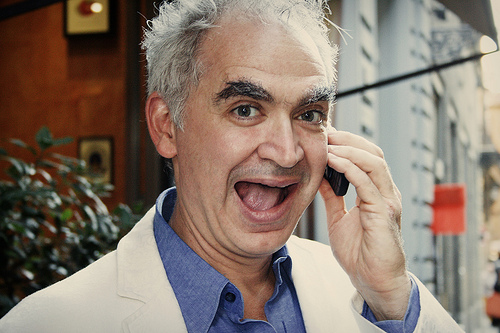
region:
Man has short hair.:
[158, 16, 249, 51]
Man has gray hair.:
[133, 21, 208, 83]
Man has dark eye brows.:
[215, 66, 336, 101]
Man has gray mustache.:
[239, 160, 334, 185]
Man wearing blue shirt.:
[204, 254, 245, 326]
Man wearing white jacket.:
[76, 267, 136, 323]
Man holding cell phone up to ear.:
[311, 111, 364, 200]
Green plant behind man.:
[17, 165, 82, 258]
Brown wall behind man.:
[14, 59, 84, 118]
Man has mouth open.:
[230, 162, 332, 232]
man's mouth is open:
[223, 171, 305, 227]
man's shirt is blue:
[156, 227, 278, 329]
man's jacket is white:
[21, 216, 447, 331]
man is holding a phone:
[311, 129, 366, 197]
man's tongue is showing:
[229, 183, 297, 225]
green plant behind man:
[3, 103, 155, 310]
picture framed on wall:
[61, 99, 118, 205]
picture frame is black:
[70, 123, 135, 203]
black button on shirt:
[221, 282, 241, 307]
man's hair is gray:
[140, 0, 400, 134]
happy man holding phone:
[114, 19, 408, 314]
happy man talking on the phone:
[123, 14, 414, 326]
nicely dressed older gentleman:
[58, 25, 425, 329]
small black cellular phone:
[324, 157, 349, 195]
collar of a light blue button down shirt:
[157, 228, 299, 332]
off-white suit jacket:
[6, 231, 453, 330]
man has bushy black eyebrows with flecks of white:
[214, 76, 338, 109]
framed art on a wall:
[67, 134, 117, 200]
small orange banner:
[432, 185, 465, 235]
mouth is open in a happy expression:
[222, 168, 301, 223]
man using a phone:
[2, 0, 467, 331]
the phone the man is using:
[324, 162, 349, 197]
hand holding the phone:
[319, 126, 406, 297]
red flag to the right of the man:
[433, 184, 466, 233]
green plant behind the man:
[2, 124, 134, 310]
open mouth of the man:
[232, 174, 302, 226]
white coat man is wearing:
[0, 207, 465, 332]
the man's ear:
[144, 89, 177, 160]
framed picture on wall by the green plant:
[74, 134, 116, 190]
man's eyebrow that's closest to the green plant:
[212, 77, 275, 104]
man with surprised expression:
[190, 25, 335, 260]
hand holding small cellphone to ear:
[150, 10, 405, 315]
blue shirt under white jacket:
[0, 180, 455, 330]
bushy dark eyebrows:
[210, 75, 330, 100]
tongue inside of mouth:
[220, 170, 295, 220]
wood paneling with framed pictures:
[0, 0, 125, 200]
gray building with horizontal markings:
[335, 0, 485, 325]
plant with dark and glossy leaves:
[0, 115, 130, 311]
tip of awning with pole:
[335, 0, 495, 96]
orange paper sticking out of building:
[421, 175, 466, 235]